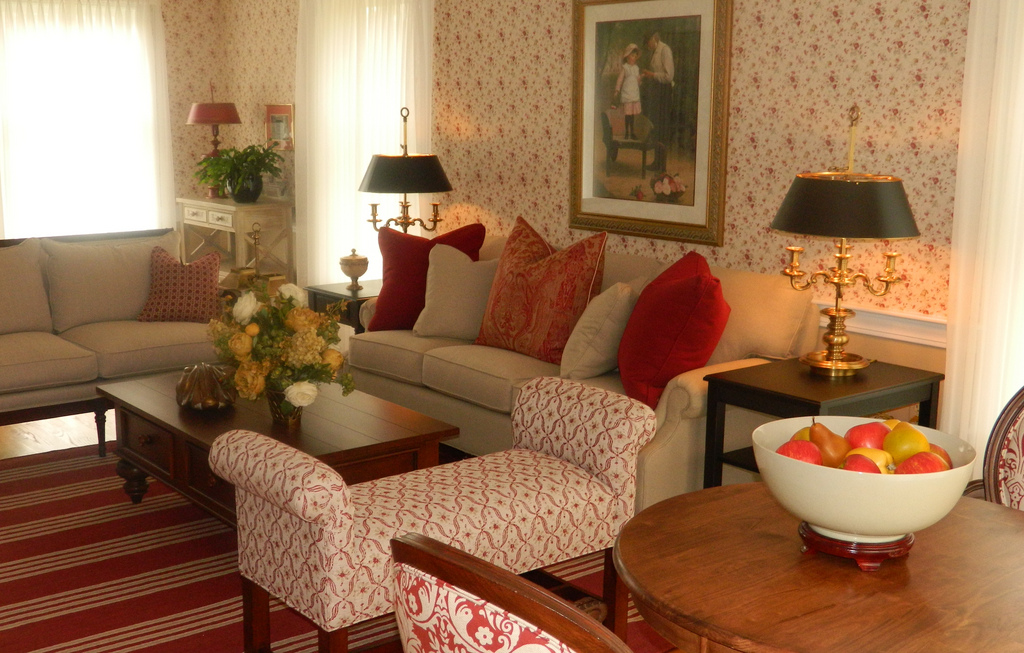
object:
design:
[457, 601, 515, 649]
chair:
[391, 532, 635, 650]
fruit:
[808, 422, 850, 467]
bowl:
[751, 415, 978, 545]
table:
[704, 350, 944, 488]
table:
[303, 279, 383, 333]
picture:
[571, 1, 724, 248]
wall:
[437, 7, 960, 309]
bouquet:
[206, 295, 355, 412]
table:
[615, 479, 1023, 651]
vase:
[265, 382, 304, 427]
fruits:
[776, 440, 822, 465]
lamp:
[775, 173, 922, 375]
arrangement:
[140, 252, 353, 424]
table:
[98, 361, 458, 506]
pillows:
[477, 216, 607, 366]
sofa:
[346, 236, 811, 514]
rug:
[36, 528, 224, 649]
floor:
[5, 439, 242, 649]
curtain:
[292, 0, 436, 308]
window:
[315, 1, 418, 282]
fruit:
[883, 422, 929, 463]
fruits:
[844, 421, 890, 448]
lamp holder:
[799, 307, 877, 377]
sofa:
[208, 375, 655, 651]